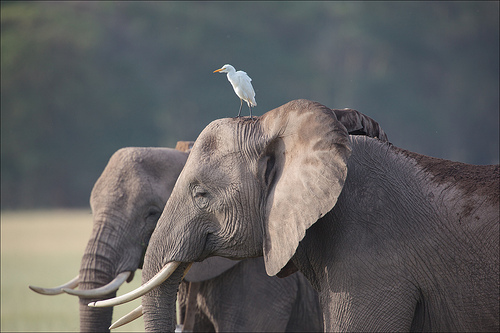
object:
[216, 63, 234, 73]
head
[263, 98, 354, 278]
ear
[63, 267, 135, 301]
trunk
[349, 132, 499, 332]
back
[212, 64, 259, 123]
bird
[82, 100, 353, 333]
head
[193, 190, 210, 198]
eye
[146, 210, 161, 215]
eye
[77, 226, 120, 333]
nose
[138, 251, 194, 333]
nose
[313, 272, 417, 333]
leg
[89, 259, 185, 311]
trunk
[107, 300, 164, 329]
trunk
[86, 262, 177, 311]
trunk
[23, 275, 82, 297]
trunk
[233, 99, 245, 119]
leg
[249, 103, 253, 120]
leg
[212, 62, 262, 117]
hat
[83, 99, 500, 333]
elephant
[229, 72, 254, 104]
plumage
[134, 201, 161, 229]
expression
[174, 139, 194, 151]
wood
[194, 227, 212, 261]
mouth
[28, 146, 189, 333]
head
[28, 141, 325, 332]
elephant